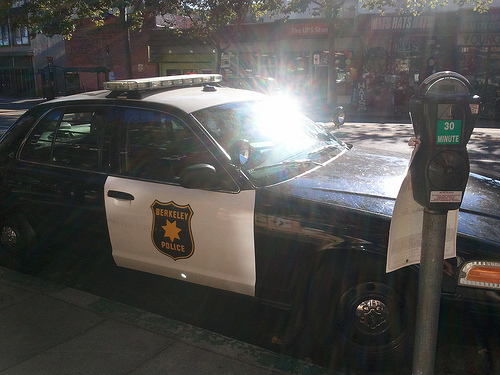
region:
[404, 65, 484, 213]
a gray metal parking meter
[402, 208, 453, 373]
a gray metal pole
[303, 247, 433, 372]
the wheel of a car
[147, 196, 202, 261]
a logo on the police car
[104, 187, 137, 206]
the handle of a car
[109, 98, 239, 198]
a car window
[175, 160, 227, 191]
a side view mirror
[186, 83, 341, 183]
a car windshield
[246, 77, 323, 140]
light shining on the car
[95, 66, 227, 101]
police lights on the car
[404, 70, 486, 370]
grey parking meter on sidewalk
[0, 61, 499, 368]
police car parked next to sidewalk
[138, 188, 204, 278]
berkely police logo on side of police vehicle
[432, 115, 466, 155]
30 minute green sign on parking meter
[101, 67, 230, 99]
rectangular lights on top of police vehicle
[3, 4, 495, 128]
line of store front buildings in front of sidewalk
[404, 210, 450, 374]
metal parking meter pole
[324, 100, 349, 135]
rear view mirror on side of police car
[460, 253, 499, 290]
orange and clear light on front of police vehicle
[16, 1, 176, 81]
green leaf tall tree on sidewalk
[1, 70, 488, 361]
Police car parked on the street.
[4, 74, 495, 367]
Police car is black and white.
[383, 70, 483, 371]
Parking meter with a paper sign hanging on it.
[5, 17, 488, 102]
Stores along the street.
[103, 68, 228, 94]
Bar light on top of the police car.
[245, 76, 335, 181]
Sun reflecting on the police car's windshield.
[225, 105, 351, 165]
Car with two emergencies side lights.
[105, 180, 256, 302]
White car door with black and golden sign on it.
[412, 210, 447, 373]
Parking meter standing on a metal pole.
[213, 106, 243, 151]
Police officer seating in the car.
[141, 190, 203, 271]
Police car logo.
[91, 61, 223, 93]
Lights on top of police car.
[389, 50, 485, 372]
Parking meter beside road.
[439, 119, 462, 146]
30 minute sign on parking meter.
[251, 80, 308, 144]
Sun glaring on the car window.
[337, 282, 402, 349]
Black and silver car rim.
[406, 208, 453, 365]
Metal pole holding parking meter.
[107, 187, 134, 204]
Door handle on car door.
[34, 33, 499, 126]
Buildings on the background.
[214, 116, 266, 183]
Officer inside police car.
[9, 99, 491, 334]
black and white police car parked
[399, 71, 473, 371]
clack parking meter beside police car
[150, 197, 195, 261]
black and gold collage police sticker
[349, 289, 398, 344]
silver metal hubcaps on black rim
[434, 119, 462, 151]
green sticker on black parking meter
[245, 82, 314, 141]
sunlight glaring on police car windshield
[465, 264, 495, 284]
right amber turn signal on police car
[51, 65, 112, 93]
wooden bus stop bench by street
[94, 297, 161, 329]
worn green paint on sidewalk by car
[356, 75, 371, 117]
store sign standing on sidewalk